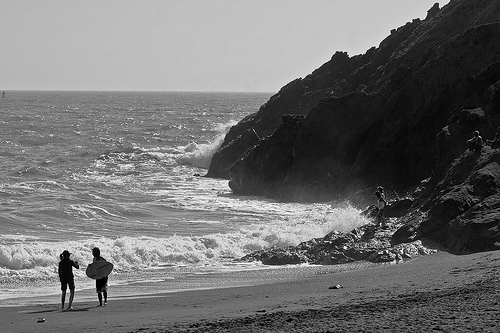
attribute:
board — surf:
[82, 256, 122, 283]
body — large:
[10, 81, 340, 261]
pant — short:
[56, 277, 77, 290]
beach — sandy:
[24, 258, 484, 328]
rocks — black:
[206, 4, 484, 225]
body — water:
[5, 91, 365, 270]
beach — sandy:
[7, 261, 481, 322]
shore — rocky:
[215, 120, 486, 270]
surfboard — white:
[84, 259, 128, 283]